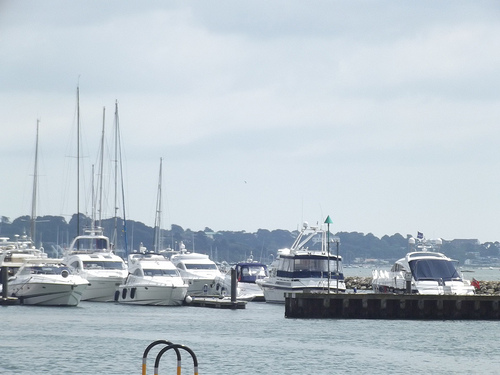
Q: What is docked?
A: Boats.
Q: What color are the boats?
A: White.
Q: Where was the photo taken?
A: Near water.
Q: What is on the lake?
A: Dock.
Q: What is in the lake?
A: Boat.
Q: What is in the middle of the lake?
A: A big boat.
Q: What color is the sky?
A: Blue.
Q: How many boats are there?
A: A cluster of boats.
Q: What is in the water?
A: Yacht.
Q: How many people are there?
A: None.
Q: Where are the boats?
A: In the water.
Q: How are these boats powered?
A: Combustion engines.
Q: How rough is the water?
A: Calm.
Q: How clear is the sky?
A: Partly cloudy.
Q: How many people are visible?
A: None.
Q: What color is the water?
A: Blue.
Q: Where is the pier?
A: To the right.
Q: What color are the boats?
A: White.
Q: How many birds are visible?
A: None.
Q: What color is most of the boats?
A: White.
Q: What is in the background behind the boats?
A: Trees.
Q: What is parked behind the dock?
A: Boats.